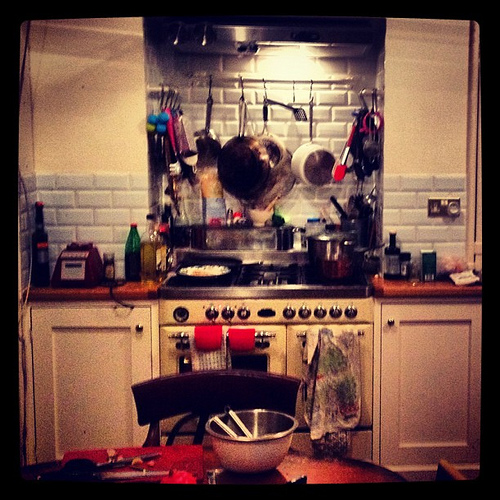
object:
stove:
[157, 264, 373, 299]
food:
[179, 265, 231, 277]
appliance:
[51, 242, 105, 287]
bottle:
[32, 201, 50, 286]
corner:
[24, 22, 48, 287]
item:
[148, 114, 158, 124]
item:
[158, 112, 170, 123]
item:
[156, 123, 166, 133]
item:
[146, 123, 155, 133]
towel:
[229, 328, 255, 352]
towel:
[195, 325, 223, 350]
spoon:
[228, 410, 252, 439]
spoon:
[213, 416, 238, 439]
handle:
[296, 330, 364, 338]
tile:
[55, 173, 95, 190]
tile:
[95, 174, 130, 190]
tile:
[38, 190, 75, 207]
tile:
[75, 190, 111, 208]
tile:
[113, 190, 148, 209]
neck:
[35, 208, 44, 233]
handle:
[388, 318, 394, 326]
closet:
[380, 303, 481, 479]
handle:
[135, 325, 143, 333]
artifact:
[217, 102, 271, 202]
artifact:
[291, 97, 336, 188]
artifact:
[331, 119, 357, 181]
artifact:
[173, 111, 191, 153]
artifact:
[195, 95, 221, 159]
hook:
[309, 79, 314, 103]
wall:
[151, 42, 375, 248]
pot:
[306, 232, 355, 280]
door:
[295, 327, 361, 441]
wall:
[382, 18, 472, 258]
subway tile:
[382, 192, 417, 208]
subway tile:
[417, 191, 467, 208]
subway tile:
[433, 174, 466, 191]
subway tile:
[399, 175, 433, 192]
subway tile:
[383, 173, 400, 190]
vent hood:
[142, 19, 386, 55]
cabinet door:
[31, 307, 151, 463]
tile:
[76, 226, 113, 245]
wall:
[25, 16, 145, 282]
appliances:
[166, 256, 243, 287]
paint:
[403, 333, 466, 433]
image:
[28, 16, 480, 480]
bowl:
[205, 409, 299, 472]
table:
[64, 444, 406, 485]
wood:
[290, 458, 356, 487]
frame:
[467, 18, 497, 466]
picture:
[17, 16, 482, 483]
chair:
[131, 368, 301, 447]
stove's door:
[160, 325, 373, 435]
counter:
[21, 279, 159, 300]